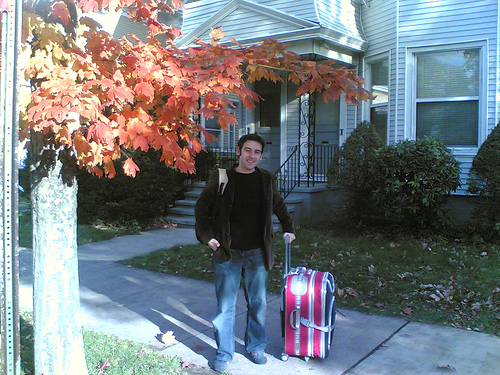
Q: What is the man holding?
A: Luggage.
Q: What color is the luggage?
A: Red.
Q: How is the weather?
A: Clear.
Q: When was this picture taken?
A: Daytime.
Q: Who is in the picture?
A: A man.